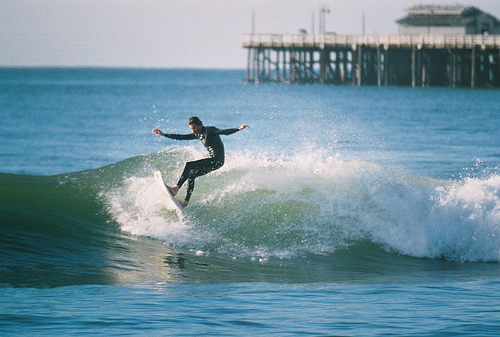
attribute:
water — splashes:
[1, 65, 498, 333]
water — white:
[136, 150, 498, 262]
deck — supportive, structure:
[245, 36, 497, 88]